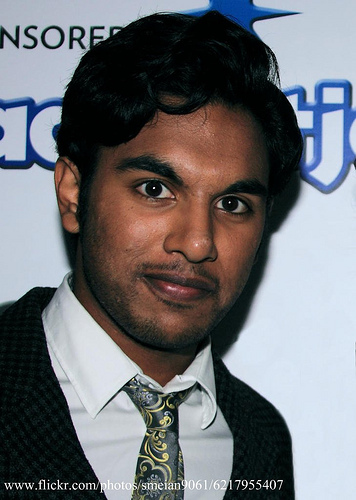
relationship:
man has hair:
[0, 10, 305, 499] [54, 11, 302, 227]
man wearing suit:
[0, 10, 305, 499] [0, 288, 293, 500]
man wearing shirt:
[0, 10, 305, 499] [42, 271, 234, 499]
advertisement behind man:
[0, 1, 355, 197] [0, 10, 305, 499]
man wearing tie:
[0, 10, 305, 499] [122, 377, 199, 500]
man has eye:
[0, 10, 305, 499] [133, 179, 176, 201]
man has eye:
[0, 10, 305, 499] [214, 196, 251, 213]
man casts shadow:
[0, 10, 305, 499] [211, 171, 299, 361]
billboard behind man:
[1, 1, 355, 499] [0, 10, 305, 499]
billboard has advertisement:
[1, 1, 355, 499] [0, 1, 355, 197]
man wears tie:
[0, 10, 305, 499] [122, 377, 199, 500]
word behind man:
[2, 79, 355, 195] [0, 10, 305, 499]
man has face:
[0, 10, 305, 499] [80, 95, 270, 350]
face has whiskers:
[80, 95, 270, 350] [80, 204, 246, 350]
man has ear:
[0, 10, 305, 499] [53, 155, 82, 234]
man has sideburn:
[0, 10, 305, 499] [75, 173, 90, 226]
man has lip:
[0, 10, 305, 499] [145, 271, 211, 289]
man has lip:
[0, 10, 305, 499] [146, 277, 212, 302]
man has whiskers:
[0, 10, 305, 499] [80, 204, 246, 350]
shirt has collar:
[42, 271, 234, 499] [41, 272, 220, 432]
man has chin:
[0, 10, 305, 499] [129, 305, 215, 349]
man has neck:
[0, 10, 305, 499] [72, 239, 203, 387]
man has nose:
[0, 10, 305, 499] [163, 193, 218, 265]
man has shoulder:
[0, 10, 305, 499] [231, 375, 290, 440]